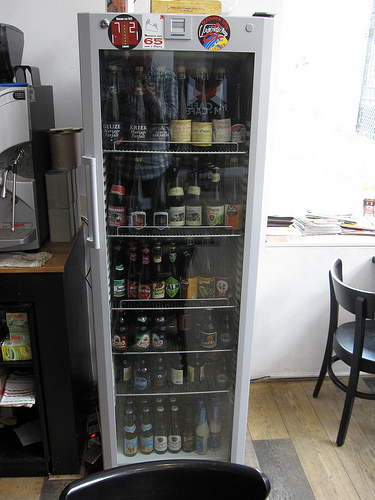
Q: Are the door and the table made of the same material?
A: No, the door is made of glass and the table is made of wood.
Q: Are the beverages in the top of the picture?
A: Yes, the beverages are in the top of the image.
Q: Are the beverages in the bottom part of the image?
A: No, the beverages are in the top of the image.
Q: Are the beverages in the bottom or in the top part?
A: The beverages are in the top of the image.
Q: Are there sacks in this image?
A: No, there are no sacks.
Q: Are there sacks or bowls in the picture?
A: No, there are no sacks or bowls.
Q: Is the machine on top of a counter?
A: Yes, the machine is on top of a counter.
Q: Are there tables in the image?
A: Yes, there is a table.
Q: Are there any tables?
A: Yes, there is a table.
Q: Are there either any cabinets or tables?
A: Yes, there is a table.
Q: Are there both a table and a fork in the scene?
A: No, there is a table but no forks.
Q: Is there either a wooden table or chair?
A: Yes, there is a wood table.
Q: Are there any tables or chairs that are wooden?
A: Yes, the table is wooden.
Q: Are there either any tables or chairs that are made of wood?
A: Yes, the table is made of wood.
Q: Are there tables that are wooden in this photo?
A: Yes, there is a wood table.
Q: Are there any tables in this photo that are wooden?
A: Yes, there is a table that is wooden.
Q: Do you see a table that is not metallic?
A: Yes, there is a wooden table.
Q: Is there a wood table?
A: Yes, there is a table that is made of wood.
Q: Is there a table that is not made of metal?
A: Yes, there is a table that is made of wood.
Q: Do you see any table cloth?
A: No, there are no tablecloths.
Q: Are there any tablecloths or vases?
A: No, there are no tablecloths or vases.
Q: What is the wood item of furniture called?
A: The piece of furniture is a table.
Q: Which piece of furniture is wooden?
A: The piece of furniture is a table.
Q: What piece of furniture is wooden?
A: The piece of furniture is a table.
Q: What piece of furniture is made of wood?
A: The piece of furniture is a table.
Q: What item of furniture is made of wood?
A: The piece of furniture is a table.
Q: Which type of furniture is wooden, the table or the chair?
A: The table is wooden.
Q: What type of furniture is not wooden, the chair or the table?
A: The chair is not wooden.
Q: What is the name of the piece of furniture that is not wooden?
A: The piece of furniture is a chair.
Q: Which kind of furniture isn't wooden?
A: The furniture is a chair.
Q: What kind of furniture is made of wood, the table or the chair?
A: The table is made of wood.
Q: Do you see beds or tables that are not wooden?
A: No, there is a table but it is wooden.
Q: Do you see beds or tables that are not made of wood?
A: No, there is a table but it is made of wood.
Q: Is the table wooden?
A: Yes, the table is wooden.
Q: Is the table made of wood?
A: Yes, the table is made of wood.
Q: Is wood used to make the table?
A: Yes, the table is made of wood.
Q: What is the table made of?
A: The table is made of wood.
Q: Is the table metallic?
A: No, the table is wooden.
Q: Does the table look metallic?
A: No, the table is wooden.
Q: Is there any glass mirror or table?
A: No, there is a table but it is wooden.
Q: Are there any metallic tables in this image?
A: No, there is a table but it is wooden.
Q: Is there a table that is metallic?
A: No, there is a table but it is wooden.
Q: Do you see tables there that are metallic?
A: No, there is a table but it is wooden.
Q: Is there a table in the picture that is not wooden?
A: No, there is a table but it is wooden.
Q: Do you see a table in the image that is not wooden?
A: No, there is a table but it is wooden.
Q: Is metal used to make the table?
A: No, the table is made of wood.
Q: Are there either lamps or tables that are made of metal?
A: No, there is a table but it is made of wood.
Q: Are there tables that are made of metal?
A: No, there is a table but it is made of wood.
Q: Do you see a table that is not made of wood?
A: No, there is a table but it is made of wood.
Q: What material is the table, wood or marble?
A: The table is made of wood.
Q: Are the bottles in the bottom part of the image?
A: Yes, the bottles are in the bottom of the image.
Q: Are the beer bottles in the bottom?
A: Yes, the bottles are in the bottom of the image.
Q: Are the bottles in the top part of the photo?
A: No, the bottles are in the bottom of the image.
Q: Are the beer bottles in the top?
A: No, the bottles are in the bottom of the image.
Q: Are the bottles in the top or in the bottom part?
A: The bottles are in the bottom of the image.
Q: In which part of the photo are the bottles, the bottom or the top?
A: The bottles are in the bottom of the image.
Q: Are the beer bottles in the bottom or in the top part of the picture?
A: The bottles are in the bottom of the image.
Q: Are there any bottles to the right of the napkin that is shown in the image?
A: Yes, there are bottles to the right of the napkin.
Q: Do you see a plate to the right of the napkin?
A: No, there are bottles to the right of the napkin.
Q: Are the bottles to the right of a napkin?
A: Yes, the bottles are to the right of a napkin.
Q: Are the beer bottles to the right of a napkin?
A: Yes, the bottles are to the right of a napkin.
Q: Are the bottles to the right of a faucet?
A: No, the bottles are to the right of a napkin.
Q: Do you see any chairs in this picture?
A: Yes, there is a chair.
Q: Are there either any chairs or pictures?
A: Yes, there is a chair.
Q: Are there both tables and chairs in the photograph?
A: Yes, there are both a chair and a table.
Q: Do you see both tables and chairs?
A: Yes, there are both a chair and a table.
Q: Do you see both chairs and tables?
A: Yes, there are both a chair and a table.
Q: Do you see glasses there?
A: No, there are no glasses.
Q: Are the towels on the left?
A: Yes, the towels are on the left of the image.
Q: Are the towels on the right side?
A: No, the towels are on the left of the image.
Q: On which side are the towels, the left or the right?
A: The towels are on the left of the image.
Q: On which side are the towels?
A: The towels are on the left of the image.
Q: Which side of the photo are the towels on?
A: The towels are on the left of the image.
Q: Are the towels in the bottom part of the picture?
A: Yes, the towels are in the bottom of the image.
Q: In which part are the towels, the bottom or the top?
A: The towels are in the bottom of the image.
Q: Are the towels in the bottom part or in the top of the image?
A: The towels are in the bottom of the image.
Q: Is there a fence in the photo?
A: No, there are no fences.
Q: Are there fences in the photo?
A: No, there are no fences.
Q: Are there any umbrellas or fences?
A: No, there are no fences or umbrellas.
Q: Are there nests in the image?
A: No, there are no nests.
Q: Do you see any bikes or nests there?
A: No, there are no nests or bikes.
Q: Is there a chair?
A: Yes, there is a chair.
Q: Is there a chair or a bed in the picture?
A: Yes, there is a chair.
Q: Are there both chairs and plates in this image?
A: No, there is a chair but no plates.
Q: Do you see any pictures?
A: No, there are no pictures.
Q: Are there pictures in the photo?
A: No, there are no pictures.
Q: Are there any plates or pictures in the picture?
A: No, there are no pictures or plates.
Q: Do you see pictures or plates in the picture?
A: No, there are no pictures or plates.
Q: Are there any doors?
A: Yes, there is a door.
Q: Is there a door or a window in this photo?
A: Yes, there is a door.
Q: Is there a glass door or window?
A: Yes, there is a glass door.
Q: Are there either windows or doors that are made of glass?
A: Yes, the door is made of glass.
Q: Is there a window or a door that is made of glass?
A: Yes, the door is made of glass.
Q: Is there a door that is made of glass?
A: Yes, there is a door that is made of glass.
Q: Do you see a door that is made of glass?
A: Yes, there is a door that is made of glass.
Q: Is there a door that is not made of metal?
A: Yes, there is a door that is made of glass.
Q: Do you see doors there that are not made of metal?
A: Yes, there is a door that is made of glass.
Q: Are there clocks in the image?
A: No, there are no clocks.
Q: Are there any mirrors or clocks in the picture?
A: No, there are no clocks or mirrors.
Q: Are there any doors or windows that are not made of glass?
A: No, there is a door but it is made of glass.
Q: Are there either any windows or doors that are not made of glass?
A: No, there is a door but it is made of glass.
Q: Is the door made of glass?
A: Yes, the door is made of glass.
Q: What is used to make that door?
A: The door is made of glass.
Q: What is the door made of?
A: The door is made of glass.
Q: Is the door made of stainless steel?
A: No, the door is made of glass.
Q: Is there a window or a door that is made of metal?
A: No, there is a door but it is made of glass.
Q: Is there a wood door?
A: No, there is a door but it is made of glass.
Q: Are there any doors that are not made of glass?
A: No, there is a door but it is made of glass.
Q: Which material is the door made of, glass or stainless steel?
A: The door is made of glass.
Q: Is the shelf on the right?
A: Yes, the shelf is on the right of the image.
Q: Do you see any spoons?
A: No, there are no spoons.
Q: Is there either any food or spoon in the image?
A: No, there are no spoons or food.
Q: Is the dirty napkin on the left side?
A: Yes, the napkin is on the left of the image.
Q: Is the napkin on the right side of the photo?
A: No, the napkin is on the left of the image.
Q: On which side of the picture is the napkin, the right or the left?
A: The napkin is on the left of the image.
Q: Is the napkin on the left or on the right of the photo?
A: The napkin is on the left of the image.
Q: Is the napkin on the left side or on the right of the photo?
A: The napkin is on the left of the image.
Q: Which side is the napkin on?
A: The napkin is on the left of the image.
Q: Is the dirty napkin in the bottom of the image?
A: Yes, the napkin is in the bottom of the image.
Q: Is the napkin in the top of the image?
A: No, the napkin is in the bottom of the image.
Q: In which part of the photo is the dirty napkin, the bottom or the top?
A: The napkin is in the bottom of the image.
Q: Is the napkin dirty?
A: Yes, the napkin is dirty.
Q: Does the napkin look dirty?
A: Yes, the napkin is dirty.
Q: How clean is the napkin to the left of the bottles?
A: The napkin is dirty.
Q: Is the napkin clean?
A: No, the napkin is dirty.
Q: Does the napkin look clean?
A: No, the napkin is dirty.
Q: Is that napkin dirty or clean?
A: The napkin is dirty.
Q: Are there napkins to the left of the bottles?
A: Yes, there is a napkin to the left of the bottles.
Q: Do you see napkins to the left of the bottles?
A: Yes, there is a napkin to the left of the bottles.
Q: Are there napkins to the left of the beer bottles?
A: Yes, there is a napkin to the left of the bottles.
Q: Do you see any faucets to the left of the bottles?
A: No, there is a napkin to the left of the bottles.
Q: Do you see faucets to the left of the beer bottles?
A: No, there is a napkin to the left of the bottles.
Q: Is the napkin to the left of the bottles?
A: Yes, the napkin is to the left of the bottles.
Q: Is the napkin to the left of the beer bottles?
A: Yes, the napkin is to the left of the bottles.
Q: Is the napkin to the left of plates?
A: No, the napkin is to the left of the bottles.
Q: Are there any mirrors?
A: No, there are no mirrors.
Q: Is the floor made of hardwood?
A: Yes, the floor is made of hardwood.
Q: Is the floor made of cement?
A: No, the floor is made of hardwood.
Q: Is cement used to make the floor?
A: No, the floor is made of hardwood.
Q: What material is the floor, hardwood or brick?
A: The floor is made of hardwood.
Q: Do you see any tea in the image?
A: Yes, there is tea.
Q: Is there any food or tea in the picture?
A: Yes, there is tea.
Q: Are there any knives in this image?
A: No, there are no knives.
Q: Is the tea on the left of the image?
A: Yes, the tea is on the left of the image.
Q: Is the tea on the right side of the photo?
A: No, the tea is on the left of the image.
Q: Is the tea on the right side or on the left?
A: The tea is on the left of the image.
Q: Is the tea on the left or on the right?
A: The tea is on the left of the image.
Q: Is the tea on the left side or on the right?
A: The tea is on the left of the image.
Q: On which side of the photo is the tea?
A: The tea is on the left of the image.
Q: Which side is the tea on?
A: The tea is on the left of the image.